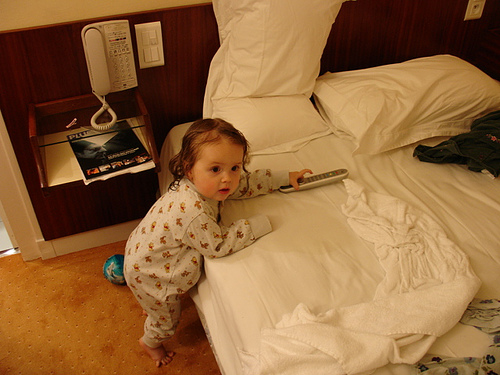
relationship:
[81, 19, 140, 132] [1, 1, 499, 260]
phone on wall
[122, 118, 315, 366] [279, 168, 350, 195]
girl holding remote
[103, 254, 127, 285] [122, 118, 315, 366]
ball behind girl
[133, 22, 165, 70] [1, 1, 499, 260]
light switches on wall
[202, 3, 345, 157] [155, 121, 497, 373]
pillow on bed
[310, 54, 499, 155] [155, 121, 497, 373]
pillow on bed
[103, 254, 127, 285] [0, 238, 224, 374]
ball on carpet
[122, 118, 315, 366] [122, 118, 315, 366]
girl in girl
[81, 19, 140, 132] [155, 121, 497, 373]
phone next to bed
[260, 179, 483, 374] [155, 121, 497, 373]
towel on bed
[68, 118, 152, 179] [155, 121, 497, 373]
magazine beside bed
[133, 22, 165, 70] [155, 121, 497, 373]
light switches beside bed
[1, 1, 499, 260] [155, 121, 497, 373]
wall beside bed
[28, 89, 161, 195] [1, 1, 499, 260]
shelf mounted on wall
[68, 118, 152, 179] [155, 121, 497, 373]
magazine next to bed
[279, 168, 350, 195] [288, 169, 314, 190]
remote in hand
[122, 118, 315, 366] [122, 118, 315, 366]
girl wearing girl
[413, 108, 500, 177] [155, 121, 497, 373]
clothing on bed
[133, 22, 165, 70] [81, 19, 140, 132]
light switches next to phone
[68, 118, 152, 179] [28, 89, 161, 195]
magazine on shelf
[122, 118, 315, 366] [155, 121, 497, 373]
girl standing by bed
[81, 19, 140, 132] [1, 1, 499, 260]
phone hanging on wall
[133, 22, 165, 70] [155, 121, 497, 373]
light switches by bed